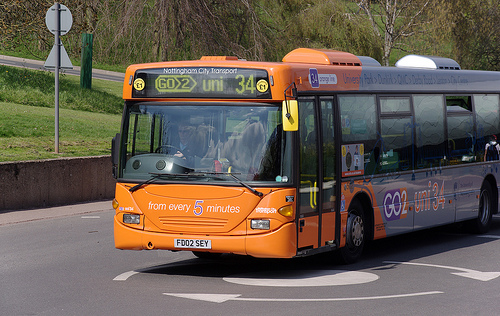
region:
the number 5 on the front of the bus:
[190, 195, 204, 220]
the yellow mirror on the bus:
[277, 92, 300, 133]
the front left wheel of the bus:
[337, 198, 373, 261]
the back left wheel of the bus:
[471, 175, 496, 231]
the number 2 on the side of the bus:
[398, 183, 408, 219]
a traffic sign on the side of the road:
[39, 0, 71, 156]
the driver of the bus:
[152, 119, 197, 179]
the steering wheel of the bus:
[152, 139, 184, 158]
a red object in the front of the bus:
[210, 155, 223, 180]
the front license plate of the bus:
[170, 234, 213, 251]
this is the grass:
[8, 70, 30, 100]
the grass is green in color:
[20, 115, 48, 140]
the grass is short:
[8, 106, 34, 115]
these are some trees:
[139, 4, 498, 35]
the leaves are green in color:
[341, 24, 371, 49]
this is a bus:
[108, 48, 498, 255]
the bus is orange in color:
[115, 230, 132, 242]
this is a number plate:
[171, 237, 216, 249]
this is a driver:
[132, 128, 216, 166]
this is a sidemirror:
[273, 93, 305, 136]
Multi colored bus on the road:
[102, 55, 492, 270]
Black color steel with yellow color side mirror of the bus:
[278, 84, 305, 131]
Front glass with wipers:
[118, 105, 280, 203]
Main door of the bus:
[300, 95, 337, 257]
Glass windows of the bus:
[348, 99, 496, 166]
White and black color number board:
[173, 235, 220, 257]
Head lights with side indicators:
[108, 195, 295, 234]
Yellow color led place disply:
[143, 75, 262, 95]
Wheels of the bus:
[345, 161, 498, 265]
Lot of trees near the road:
[16, 0, 448, 52]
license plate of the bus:
[168, 233, 218, 250]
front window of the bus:
[122, 105, 285, 186]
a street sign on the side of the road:
[33, 7, 79, 162]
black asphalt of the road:
[21, 228, 103, 310]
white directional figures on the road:
[91, 264, 469, 305]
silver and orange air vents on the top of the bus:
[278, 37, 473, 79]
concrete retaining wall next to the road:
[2, 153, 107, 206]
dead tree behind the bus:
[334, 0, 433, 54]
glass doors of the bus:
[283, 85, 350, 256]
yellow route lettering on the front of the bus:
[145, 71, 257, 98]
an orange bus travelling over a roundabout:
[104, 40, 497, 272]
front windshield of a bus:
[114, 97, 295, 186]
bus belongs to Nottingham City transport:
[149, 64, 241, 78]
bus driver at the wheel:
[151, 122, 199, 164]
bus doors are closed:
[289, 90, 344, 257]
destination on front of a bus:
[149, 73, 226, 95]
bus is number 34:
[232, 71, 259, 98]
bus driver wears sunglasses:
[169, 119, 195, 146]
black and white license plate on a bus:
[170, 235, 213, 252]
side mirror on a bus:
[275, 81, 301, 137]